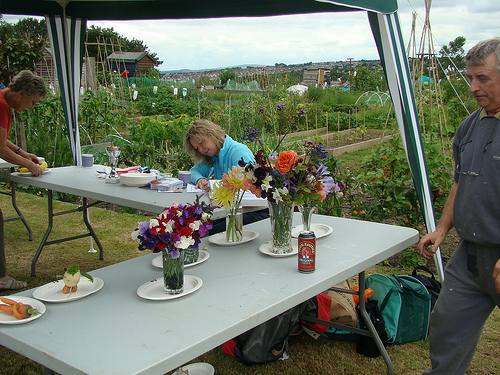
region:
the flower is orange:
[276, 154, 293, 166]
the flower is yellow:
[218, 189, 231, 202]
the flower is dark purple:
[200, 226, 207, 235]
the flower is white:
[181, 239, 193, 246]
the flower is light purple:
[139, 220, 146, 233]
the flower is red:
[180, 228, 190, 235]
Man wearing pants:
[420, 236, 497, 373]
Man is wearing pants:
[423, 232, 495, 372]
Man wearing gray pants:
[422, 237, 499, 373]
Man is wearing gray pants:
[422, 230, 498, 373]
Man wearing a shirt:
[442, 101, 498, 249]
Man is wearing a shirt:
[445, 105, 493, 250]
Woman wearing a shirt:
[187, 134, 257, 187]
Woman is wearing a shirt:
[186, 132, 263, 191]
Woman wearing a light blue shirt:
[188, 130, 258, 187]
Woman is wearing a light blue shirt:
[186, 134, 258, 188]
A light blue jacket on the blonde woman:
[178, 137, 268, 192]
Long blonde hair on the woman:
[182, 117, 230, 157]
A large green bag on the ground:
[358, 268, 458, 349]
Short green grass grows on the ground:
[102, 214, 124, 238]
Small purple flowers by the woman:
[242, 124, 266, 146]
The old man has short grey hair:
[462, 37, 497, 76]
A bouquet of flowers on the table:
[142, 200, 205, 290]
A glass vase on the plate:
[160, 250, 188, 295]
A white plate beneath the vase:
[142, 273, 204, 303]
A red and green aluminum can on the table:
[295, 227, 322, 274]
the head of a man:
[450, 47, 497, 122]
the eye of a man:
[457, 53, 497, 95]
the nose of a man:
[452, 63, 497, 99]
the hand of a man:
[408, 203, 470, 262]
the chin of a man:
[456, 79, 494, 124]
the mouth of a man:
[453, 83, 497, 117]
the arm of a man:
[403, 140, 489, 280]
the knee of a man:
[410, 290, 482, 359]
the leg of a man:
[420, 257, 490, 369]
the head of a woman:
[171, 107, 241, 174]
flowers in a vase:
[131, 192, 197, 305]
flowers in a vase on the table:
[134, 206, 200, 308]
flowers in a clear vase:
[134, 200, 207, 297]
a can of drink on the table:
[309, 220, 324, 315]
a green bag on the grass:
[365, 260, 432, 362]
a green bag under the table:
[363, 206, 431, 353]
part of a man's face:
[453, 25, 495, 130]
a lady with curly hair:
[166, 112, 265, 199]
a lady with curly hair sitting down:
[170, 84, 257, 192]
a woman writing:
[172, 111, 257, 192]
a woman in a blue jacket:
[174, 105, 261, 194]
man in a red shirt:
[2, 67, 57, 203]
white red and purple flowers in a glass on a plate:
[135, 205, 204, 301]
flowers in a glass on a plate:
[287, 143, 342, 240]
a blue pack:
[357, 261, 436, 350]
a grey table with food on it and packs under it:
[4, 196, 428, 373]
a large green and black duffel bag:
[364, 266, 438, 350]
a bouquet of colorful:
[247, 128, 333, 258]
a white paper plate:
[138, 269, 201, 296]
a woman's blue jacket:
[183, 134, 261, 188]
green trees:
[3, 20, 40, 39]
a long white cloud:
[140, 20, 375, 63]